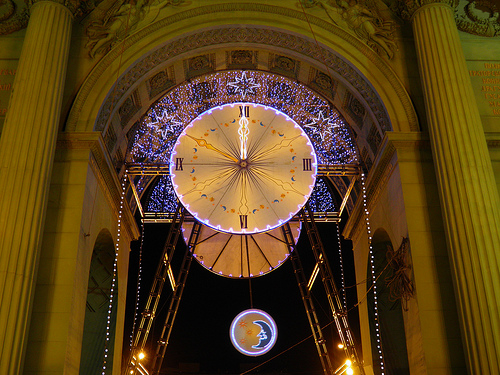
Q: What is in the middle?
A: Clock.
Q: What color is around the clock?
A: Blue.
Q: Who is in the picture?
A: No one.